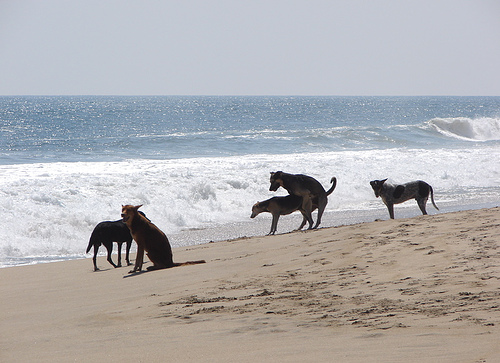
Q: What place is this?
A: It is a beach.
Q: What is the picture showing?
A: It is showing a beach.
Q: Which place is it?
A: It is a beach.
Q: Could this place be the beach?
A: Yes, it is the beach.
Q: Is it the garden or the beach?
A: It is the beach.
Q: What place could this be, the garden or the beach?
A: It is the beach.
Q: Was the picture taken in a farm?
A: No, the picture was taken in a beach.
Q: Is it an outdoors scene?
A: Yes, it is outdoors.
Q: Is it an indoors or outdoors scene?
A: It is outdoors.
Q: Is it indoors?
A: No, it is outdoors.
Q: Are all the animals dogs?
A: Yes, all the animals are dogs.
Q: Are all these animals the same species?
A: Yes, all the animals are dogs.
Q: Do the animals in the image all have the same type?
A: Yes, all the animals are dogs.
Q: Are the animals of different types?
A: No, all the animals are dogs.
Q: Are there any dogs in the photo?
A: Yes, there is a dog.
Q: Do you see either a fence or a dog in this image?
A: Yes, there is a dog.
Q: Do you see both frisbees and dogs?
A: No, there is a dog but no frisbees.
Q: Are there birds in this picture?
A: No, there are no birds.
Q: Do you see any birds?
A: No, there are no birds.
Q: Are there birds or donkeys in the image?
A: No, there are no birds or donkeys.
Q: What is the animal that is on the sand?
A: The animal is a dog.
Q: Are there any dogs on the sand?
A: Yes, there is a dog on the sand.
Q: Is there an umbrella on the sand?
A: No, there is a dog on the sand.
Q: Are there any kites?
A: No, there are no kites.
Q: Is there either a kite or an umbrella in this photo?
A: No, there are no kites or umbrellas.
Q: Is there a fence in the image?
A: No, there are no fences.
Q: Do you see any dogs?
A: Yes, there is a dog.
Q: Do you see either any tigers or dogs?
A: Yes, there is a dog.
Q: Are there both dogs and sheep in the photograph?
A: No, there is a dog but no sheep.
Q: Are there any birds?
A: No, there are no birds.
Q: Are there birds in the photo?
A: No, there are no birds.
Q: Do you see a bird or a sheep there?
A: No, there are no birds or sheep.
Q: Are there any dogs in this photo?
A: Yes, there is a dog.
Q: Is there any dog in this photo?
A: Yes, there is a dog.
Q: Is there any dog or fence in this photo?
A: Yes, there is a dog.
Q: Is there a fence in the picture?
A: No, there are no fences.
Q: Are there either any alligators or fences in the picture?
A: No, there are no fences or alligators.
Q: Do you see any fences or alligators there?
A: No, there are no fences or alligators.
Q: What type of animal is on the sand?
A: The animal is a dog.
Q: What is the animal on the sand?
A: The animal is a dog.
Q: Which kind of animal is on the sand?
A: The animal is a dog.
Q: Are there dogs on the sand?
A: Yes, there is a dog on the sand.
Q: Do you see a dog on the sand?
A: Yes, there is a dog on the sand.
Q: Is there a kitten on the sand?
A: No, there is a dog on the sand.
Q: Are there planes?
A: No, there are no planes.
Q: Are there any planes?
A: No, there are no planes.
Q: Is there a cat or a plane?
A: No, there are no airplanes or cats.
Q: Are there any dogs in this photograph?
A: Yes, there is a dog.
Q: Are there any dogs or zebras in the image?
A: Yes, there is a dog.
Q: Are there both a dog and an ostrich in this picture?
A: No, there is a dog but no ostriches.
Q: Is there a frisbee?
A: No, there are no frisbees.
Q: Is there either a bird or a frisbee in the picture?
A: No, there are no frisbees or birds.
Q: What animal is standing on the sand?
A: The dog is standing on the sand.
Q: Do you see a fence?
A: No, there are no fences.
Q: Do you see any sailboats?
A: No, there are no sailboats.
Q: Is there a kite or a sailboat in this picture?
A: No, there are no sailboats or kites.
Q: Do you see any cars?
A: No, there are no cars.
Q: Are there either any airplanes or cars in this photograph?
A: No, there are no cars or airplanes.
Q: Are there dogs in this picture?
A: Yes, there are dogs.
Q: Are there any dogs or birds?
A: Yes, there are dogs.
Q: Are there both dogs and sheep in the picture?
A: No, there are dogs but no sheep.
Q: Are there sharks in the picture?
A: No, there are no sharks.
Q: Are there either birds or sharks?
A: No, there are no sharks or birds.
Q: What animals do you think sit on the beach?
A: The animals are dogs.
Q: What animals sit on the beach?
A: The animals are dogs.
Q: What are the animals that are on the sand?
A: The animals are dogs.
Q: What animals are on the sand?
A: The animals are dogs.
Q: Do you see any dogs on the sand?
A: Yes, there are dogs on the sand.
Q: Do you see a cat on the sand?
A: No, there are dogs on the sand.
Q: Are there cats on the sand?
A: No, there are dogs on the sand.